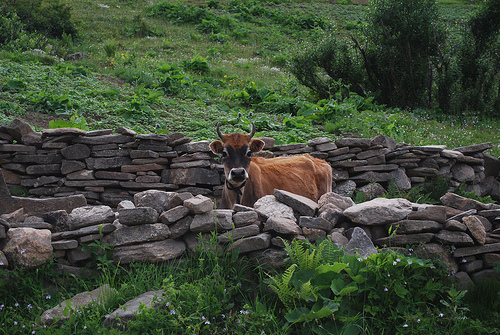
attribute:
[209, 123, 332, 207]
cow — brown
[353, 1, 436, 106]
large — green tree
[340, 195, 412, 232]
large — grey stone